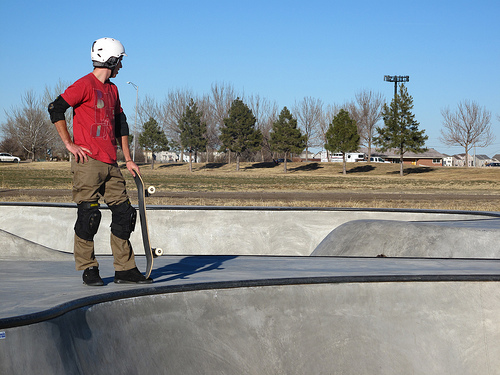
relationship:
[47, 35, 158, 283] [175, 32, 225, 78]
kid on side of building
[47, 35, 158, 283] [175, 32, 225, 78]
kid playing in snow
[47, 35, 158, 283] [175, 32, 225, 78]
kid eating hen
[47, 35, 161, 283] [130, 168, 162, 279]
kid with skateboard